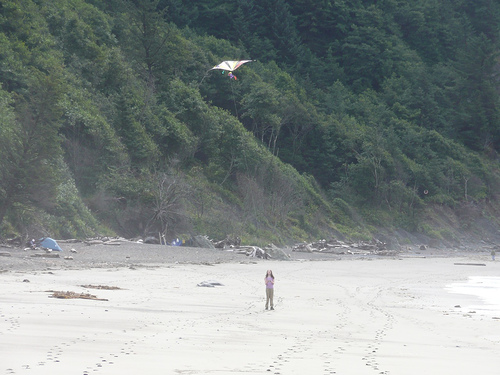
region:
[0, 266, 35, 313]
person standin on beach flying kite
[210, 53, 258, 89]
kite flown in air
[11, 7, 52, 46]
green bushes on hill side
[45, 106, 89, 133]
green bushes on hill side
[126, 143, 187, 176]
green bushes on hill side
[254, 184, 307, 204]
green bushes on hill side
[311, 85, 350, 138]
green bushes on hill side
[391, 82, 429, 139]
green bushes on hill side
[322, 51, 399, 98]
green bushes on hill side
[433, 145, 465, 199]
green bushes on hill side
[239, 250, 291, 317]
girl flying kite on beach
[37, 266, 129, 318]
dead seaweed washed up on beach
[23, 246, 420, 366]
tracks up and down beach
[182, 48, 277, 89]
kite being flown by woman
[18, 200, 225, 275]
trash amongst rock and bushes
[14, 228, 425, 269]
rocks and tree branches along beach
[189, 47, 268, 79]
colorful kite in flight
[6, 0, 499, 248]
forest along beach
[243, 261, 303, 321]
woman in pink shirt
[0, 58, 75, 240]
tree growing toward ocean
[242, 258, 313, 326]
A girl on the beach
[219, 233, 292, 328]
Girl is looking up to the sky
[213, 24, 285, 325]
Girl is flying a kite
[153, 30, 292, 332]
A girl on the beach flying a kite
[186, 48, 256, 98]
The kite is white with a small tail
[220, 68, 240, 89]
The tail is but very colorful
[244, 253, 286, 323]
The girl seems small on the beach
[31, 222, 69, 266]
Something blue near the tree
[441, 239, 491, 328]
water coming on to the beach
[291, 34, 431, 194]
Trees going up the side of mountain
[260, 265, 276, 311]
a little girl on a beach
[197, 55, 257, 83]
a kite flying in the air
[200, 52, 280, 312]
a girl flying a kite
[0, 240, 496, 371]
a beach by the woods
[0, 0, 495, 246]
woodlands in the background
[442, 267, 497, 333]
ocean by the beach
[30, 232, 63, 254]
tent on the beach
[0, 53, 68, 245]
a tree leaning over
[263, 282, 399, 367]
footprints on the beach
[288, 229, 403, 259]
a pile of driftwood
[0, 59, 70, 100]
kite flown by person on beach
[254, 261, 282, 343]
person on beach flying kite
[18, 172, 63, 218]
green and brown plants on hillside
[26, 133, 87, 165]
green and brown plants on hillside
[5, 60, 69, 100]
green and brown plants on hillside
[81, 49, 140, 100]
green and brown plants on hillside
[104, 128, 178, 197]
green and brown plants on hillside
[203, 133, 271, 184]
green and brown plants on hillside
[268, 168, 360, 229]
green and brown plants on hillside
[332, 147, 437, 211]
green and brown plants on hillside